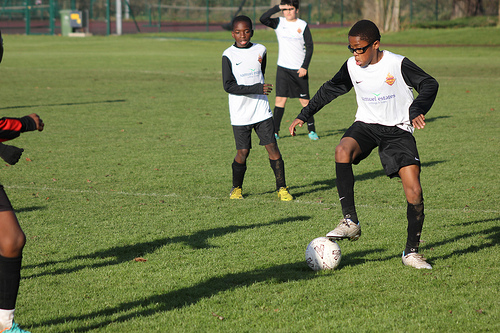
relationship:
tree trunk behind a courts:
[451, 0, 492, 30] [0, 9, 499, 332]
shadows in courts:
[55, 214, 292, 326] [0, 9, 499, 332]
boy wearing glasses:
[288, 19, 440, 268] [347, 41, 381, 53]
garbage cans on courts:
[54, 4, 93, 39] [6, 9, 244, 40]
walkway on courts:
[1, 17, 361, 37] [9, 7, 496, 322]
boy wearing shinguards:
[288, 19, 440, 268] [402, 199, 426, 256]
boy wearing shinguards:
[288, 19, 440, 268] [333, 158, 358, 223]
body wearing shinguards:
[221, 15, 294, 201] [265, 152, 287, 190]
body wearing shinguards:
[221, 15, 294, 201] [230, 157, 248, 189]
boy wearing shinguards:
[258, 0, 320, 141] [270, 102, 285, 132]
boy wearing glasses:
[288, 19, 440, 268] [344, 37, 394, 75]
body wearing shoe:
[221, 15, 294, 201] [273, 186, 294, 202]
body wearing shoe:
[221, 15, 294, 201] [225, 186, 245, 201]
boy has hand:
[258, 1, 321, 141] [276, 3, 285, 10]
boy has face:
[258, 1, 321, 141] [279, 4, 298, 20]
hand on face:
[276, 3, 285, 10] [279, 4, 298, 20]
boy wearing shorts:
[288, 19, 440, 269] [335, 116, 425, 178]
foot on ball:
[327, 218, 358, 240] [310, 236, 337, 270]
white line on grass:
[0, 170, 498, 216] [0, 28, 497, 330]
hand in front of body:
[222, 55, 273, 90] [222, 19, 294, 200]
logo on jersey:
[378, 71, 412, 92] [298, 49, 439, 133]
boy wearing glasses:
[288, 19, 440, 269] [346, 44, 371, 54]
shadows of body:
[75, 194, 315, 329] [221, 15, 294, 201]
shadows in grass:
[75, 194, 315, 329] [0, 28, 497, 330]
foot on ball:
[323, 218, 361, 237] [306, 236, 343, 273]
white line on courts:
[0, 184, 499, 214] [0, 9, 499, 332]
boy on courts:
[288, 19, 440, 268] [0, 9, 499, 332]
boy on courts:
[258, 0, 320, 141] [0, 9, 499, 332]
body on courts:
[221, 15, 294, 201] [0, 9, 499, 332]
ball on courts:
[306, 236, 343, 273] [0, 9, 499, 332]